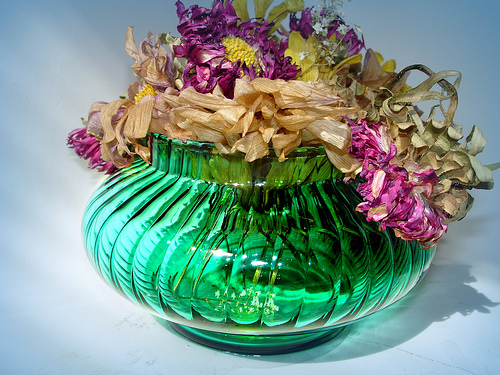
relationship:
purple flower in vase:
[348, 130, 445, 253] [61, 125, 438, 372]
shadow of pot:
[391, 242, 484, 352] [59, 109, 498, 355]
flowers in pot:
[65, 1, 499, 249] [79, 130, 436, 356]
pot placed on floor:
[59, 109, 498, 355] [2, 1, 477, 372]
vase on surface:
[61, 125, 438, 372] [2, 126, 497, 371]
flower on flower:
[218, 33, 258, 65] [168, 0, 300, 100]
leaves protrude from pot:
[79, 22, 499, 223] [79, 130, 436, 356]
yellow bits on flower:
[223, 34, 261, 73] [218, 33, 258, 65]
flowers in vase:
[65, 1, 499, 249] [61, 125, 438, 372]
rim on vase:
[145, 127, 327, 155] [61, 125, 438, 372]